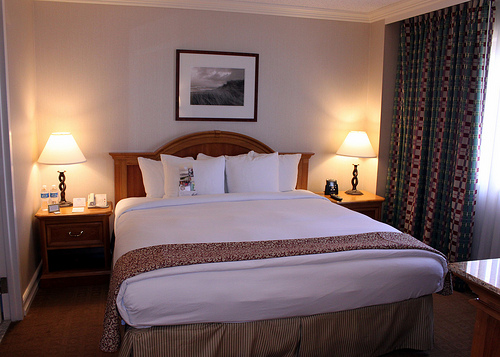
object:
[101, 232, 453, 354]
strip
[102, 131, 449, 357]
bed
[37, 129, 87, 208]
lamp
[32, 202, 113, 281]
stand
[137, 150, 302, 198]
pillows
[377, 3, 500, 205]
window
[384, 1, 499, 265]
curtains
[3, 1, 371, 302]
wall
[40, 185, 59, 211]
bottles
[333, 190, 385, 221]
table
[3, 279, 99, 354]
carpet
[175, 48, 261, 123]
photo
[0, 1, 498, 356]
room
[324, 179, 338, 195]
telephone